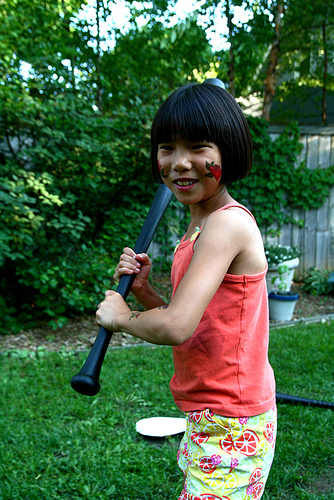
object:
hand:
[95, 289, 132, 331]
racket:
[135, 416, 186, 437]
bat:
[71, 78, 226, 396]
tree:
[262, 0, 334, 121]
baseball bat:
[276, 392, 334, 409]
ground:
[0, 271, 334, 499]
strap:
[216, 203, 256, 224]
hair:
[150, 81, 252, 184]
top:
[169, 203, 276, 418]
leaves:
[3, 344, 72, 371]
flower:
[210, 164, 223, 182]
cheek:
[191, 147, 223, 197]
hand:
[113, 245, 152, 292]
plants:
[257, 136, 325, 227]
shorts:
[177, 404, 278, 498]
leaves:
[0, 1, 334, 345]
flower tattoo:
[204, 160, 222, 183]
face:
[157, 137, 222, 205]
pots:
[268, 290, 299, 321]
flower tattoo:
[158, 160, 168, 179]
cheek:
[157, 149, 173, 192]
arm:
[134, 284, 168, 311]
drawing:
[204, 160, 222, 182]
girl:
[95, 82, 278, 499]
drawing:
[129, 311, 141, 321]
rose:
[135, 312, 139, 318]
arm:
[115, 211, 238, 346]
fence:
[145, 126, 334, 283]